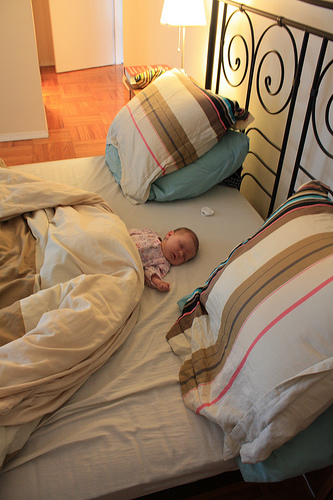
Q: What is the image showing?
A: It is showing a bedroom.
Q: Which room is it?
A: It is a bedroom.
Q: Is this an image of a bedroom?
A: Yes, it is showing a bedroom.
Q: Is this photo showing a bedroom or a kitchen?
A: It is showing a bedroom.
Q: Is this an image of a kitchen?
A: No, the picture is showing a bedroom.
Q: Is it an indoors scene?
A: Yes, it is indoors.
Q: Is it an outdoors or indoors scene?
A: It is indoors.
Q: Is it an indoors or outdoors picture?
A: It is indoors.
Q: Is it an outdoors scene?
A: No, it is indoors.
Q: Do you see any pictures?
A: No, there are no pictures.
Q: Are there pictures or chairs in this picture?
A: No, there are no pictures or chairs.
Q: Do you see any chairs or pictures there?
A: No, there are no pictures or chairs.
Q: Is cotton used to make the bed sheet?
A: Yes, the bed sheet is made of cotton.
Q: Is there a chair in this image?
A: No, there are no chairs.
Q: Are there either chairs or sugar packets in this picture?
A: No, there are no chairs or sugar packets.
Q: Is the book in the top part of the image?
A: Yes, the book is in the top of the image.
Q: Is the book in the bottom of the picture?
A: No, the book is in the top of the image.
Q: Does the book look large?
A: Yes, the book is large.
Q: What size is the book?
A: The book is large.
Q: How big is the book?
A: The book is large.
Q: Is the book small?
A: No, the book is large.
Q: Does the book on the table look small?
A: No, the book is large.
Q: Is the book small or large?
A: The book is large.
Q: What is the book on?
A: The book is on the table.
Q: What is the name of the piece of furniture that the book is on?
A: The piece of furniture is a table.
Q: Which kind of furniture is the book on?
A: The book is on the table.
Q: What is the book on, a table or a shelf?
A: The book is on a table.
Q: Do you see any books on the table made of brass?
A: Yes, there is a book on the table.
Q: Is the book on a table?
A: Yes, the book is on a table.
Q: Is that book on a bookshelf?
A: No, the book is on a table.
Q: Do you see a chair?
A: No, there are no chairs.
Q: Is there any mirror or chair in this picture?
A: No, there are no chairs or mirrors.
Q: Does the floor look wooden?
A: Yes, the floor is wooden.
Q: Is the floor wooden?
A: Yes, the floor is wooden.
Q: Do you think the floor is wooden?
A: Yes, the floor is wooden.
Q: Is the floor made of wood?
A: Yes, the floor is made of wood.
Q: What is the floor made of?
A: The floor is made of wood.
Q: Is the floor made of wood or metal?
A: The floor is made of wood.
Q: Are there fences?
A: No, there are no fences.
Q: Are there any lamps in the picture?
A: Yes, there is a lamp.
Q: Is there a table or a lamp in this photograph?
A: Yes, there is a lamp.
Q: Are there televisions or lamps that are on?
A: Yes, the lamp is on.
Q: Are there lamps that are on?
A: Yes, there is a lamp that is on.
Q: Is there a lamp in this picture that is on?
A: Yes, there is a lamp that is on.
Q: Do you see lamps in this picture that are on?
A: Yes, there is a lamp that is on.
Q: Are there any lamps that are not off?
A: Yes, there is a lamp that is on.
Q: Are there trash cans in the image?
A: No, there are no trash cans.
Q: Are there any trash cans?
A: No, there are no trash cans.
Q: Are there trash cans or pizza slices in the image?
A: No, there are no trash cans or pizza slices.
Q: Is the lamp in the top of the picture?
A: Yes, the lamp is in the top of the image.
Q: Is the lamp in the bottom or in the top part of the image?
A: The lamp is in the top of the image.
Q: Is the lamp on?
A: Yes, the lamp is on.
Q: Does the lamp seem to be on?
A: Yes, the lamp is on.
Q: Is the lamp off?
A: No, the lamp is on.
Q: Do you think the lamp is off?
A: No, the lamp is on.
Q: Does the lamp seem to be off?
A: No, the lamp is on.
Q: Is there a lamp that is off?
A: No, there is a lamp but it is on.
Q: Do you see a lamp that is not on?
A: No, there is a lamp but it is on.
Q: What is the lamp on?
A: The lamp is on the table.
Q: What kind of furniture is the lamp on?
A: The lamp is on the table.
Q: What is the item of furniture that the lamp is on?
A: The piece of furniture is a table.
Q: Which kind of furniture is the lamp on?
A: The lamp is on the table.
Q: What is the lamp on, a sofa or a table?
A: The lamp is on a table.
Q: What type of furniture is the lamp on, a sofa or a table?
A: The lamp is on a table.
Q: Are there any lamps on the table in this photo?
A: Yes, there is a lamp on the table.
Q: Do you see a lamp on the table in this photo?
A: Yes, there is a lamp on the table.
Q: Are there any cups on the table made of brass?
A: No, there is a lamp on the table.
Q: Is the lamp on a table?
A: Yes, the lamp is on a table.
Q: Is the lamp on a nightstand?
A: No, the lamp is on a table.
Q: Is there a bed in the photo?
A: Yes, there is a bed.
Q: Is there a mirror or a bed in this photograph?
A: Yes, there is a bed.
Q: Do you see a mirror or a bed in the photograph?
A: Yes, there is a bed.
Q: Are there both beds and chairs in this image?
A: No, there is a bed but no chairs.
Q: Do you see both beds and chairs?
A: No, there is a bed but no chairs.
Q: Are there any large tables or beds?
A: Yes, there is a large bed.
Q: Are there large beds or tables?
A: Yes, there is a large bed.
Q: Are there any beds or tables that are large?
A: Yes, the bed is large.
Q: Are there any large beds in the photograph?
A: Yes, there is a large bed.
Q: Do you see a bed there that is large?
A: Yes, there is a bed that is large.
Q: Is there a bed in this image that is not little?
A: Yes, there is a large bed.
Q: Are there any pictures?
A: No, there are no pictures.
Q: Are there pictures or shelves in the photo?
A: No, there are no pictures or shelves.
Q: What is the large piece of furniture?
A: The piece of furniture is a bed.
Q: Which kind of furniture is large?
A: The furniture is a bed.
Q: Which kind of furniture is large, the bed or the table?
A: The bed is large.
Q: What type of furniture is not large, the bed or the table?
A: The table is not large.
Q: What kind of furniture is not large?
A: The furniture is a table.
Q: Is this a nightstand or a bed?
A: This is a bed.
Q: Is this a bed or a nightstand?
A: This is a bed.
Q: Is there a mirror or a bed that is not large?
A: No, there is a bed but it is large.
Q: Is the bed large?
A: Yes, the bed is large.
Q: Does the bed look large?
A: Yes, the bed is large.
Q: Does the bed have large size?
A: Yes, the bed is large.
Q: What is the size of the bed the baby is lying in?
A: The bed is large.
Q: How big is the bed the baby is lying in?
A: The bed is large.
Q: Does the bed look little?
A: No, the bed is large.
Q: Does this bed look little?
A: No, the bed is large.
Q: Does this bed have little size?
A: No, the bed is large.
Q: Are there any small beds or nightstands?
A: No, there is a bed but it is large.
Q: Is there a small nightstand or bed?
A: No, there is a bed but it is large.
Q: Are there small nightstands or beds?
A: No, there is a bed but it is large.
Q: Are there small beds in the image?
A: No, there is a bed but it is large.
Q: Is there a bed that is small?
A: No, there is a bed but it is large.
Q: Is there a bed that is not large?
A: No, there is a bed but it is large.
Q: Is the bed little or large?
A: The bed is large.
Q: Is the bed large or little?
A: The bed is large.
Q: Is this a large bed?
A: Yes, this is a large bed.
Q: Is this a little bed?
A: No, this is a large bed.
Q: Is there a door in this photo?
A: Yes, there is a door.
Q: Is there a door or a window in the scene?
A: Yes, there is a door.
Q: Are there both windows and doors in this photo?
A: No, there is a door but no windows.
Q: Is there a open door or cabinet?
A: Yes, there is an open door.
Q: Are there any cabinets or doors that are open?
A: Yes, the door is open.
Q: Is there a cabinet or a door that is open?
A: Yes, the door is open.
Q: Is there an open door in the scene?
A: Yes, there is an open door.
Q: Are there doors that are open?
A: Yes, there is a door that is open.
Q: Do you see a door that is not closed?
A: Yes, there is a open door.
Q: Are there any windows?
A: No, there are no windows.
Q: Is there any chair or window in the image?
A: No, there are no windows or chairs.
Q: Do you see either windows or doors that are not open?
A: No, there is a door but it is open.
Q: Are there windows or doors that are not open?
A: No, there is a door but it is open.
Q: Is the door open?
A: Yes, the door is open.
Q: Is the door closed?
A: No, the door is open.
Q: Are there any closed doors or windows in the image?
A: No, there is a door but it is open.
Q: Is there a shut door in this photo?
A: No, there is a door but it is open.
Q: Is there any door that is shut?
A: No, there is a door but it is open.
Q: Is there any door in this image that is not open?
A: No, there is a door but it is open.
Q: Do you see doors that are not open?
A: No, there is a door but it is open.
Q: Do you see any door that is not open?
A: No, there is a door but it is open.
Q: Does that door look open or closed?
A: The door is open.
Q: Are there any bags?
A: Yes, there is a bag.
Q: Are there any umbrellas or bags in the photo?
A: Yes, there is a bag.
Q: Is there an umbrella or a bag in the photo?
A: Yes, there is a bag.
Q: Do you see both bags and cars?
A: No, there is a bag but no cars.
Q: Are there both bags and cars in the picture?
A: No, there is a bag but no cars.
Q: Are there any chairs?
A: No, there are no chairs.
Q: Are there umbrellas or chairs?
A: No, there are no chairs or umbrellas.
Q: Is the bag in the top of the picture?
A: Yes, the bag is in the top of the image.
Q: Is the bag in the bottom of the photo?
A: No, the bag is in the top of the image.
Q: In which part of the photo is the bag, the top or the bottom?
A: The bag is in the top of the image.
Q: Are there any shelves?
A: No, there are no shelves.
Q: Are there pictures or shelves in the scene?
A: No, there are no shelves or pictures.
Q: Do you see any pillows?
A: Yes, there is a pillow.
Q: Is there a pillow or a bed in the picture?
A: Yes, there is a pillow.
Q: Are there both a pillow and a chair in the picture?
A: No, there is a pillow but no chairs.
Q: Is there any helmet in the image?
A: No, there are no helmets.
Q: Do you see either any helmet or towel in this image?
A: No, there are no helmets or towels.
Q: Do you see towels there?
A: No, there are no towels.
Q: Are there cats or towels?
A: No, there are no towels or cats.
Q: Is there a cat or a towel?
A: No, there are no towels or cats.